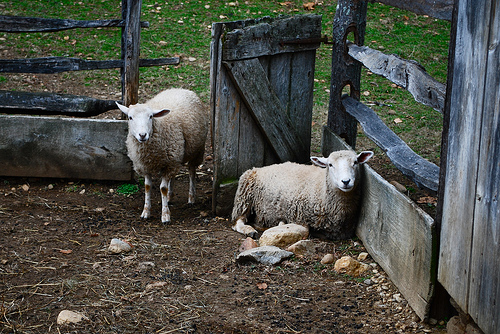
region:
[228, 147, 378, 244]
White sheep laying on the ground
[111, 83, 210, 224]
White sheep on its feet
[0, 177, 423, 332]
Ground of pebbles and soil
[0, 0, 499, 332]
Pen of wooden plants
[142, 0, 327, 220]
Open door of a pen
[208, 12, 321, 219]
Wooden frame of a door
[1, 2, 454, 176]
Short green grass with dry leaves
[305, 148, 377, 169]
Straight pointed ears of a sheep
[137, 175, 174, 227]
White legs with colored knees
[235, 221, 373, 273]
Huddled pieces of rock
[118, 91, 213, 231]
white sheep in wood pen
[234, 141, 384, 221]
white sheep in wood pen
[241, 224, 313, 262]
small rocks on pen floor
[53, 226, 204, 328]
brown sticks and hay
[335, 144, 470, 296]
wooden plans around pen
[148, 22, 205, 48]
green grass growing around pen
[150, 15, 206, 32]
dead leaves laying in grass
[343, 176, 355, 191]
black nsoe of white sheep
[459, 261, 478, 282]
nails in wooden boards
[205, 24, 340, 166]
small door of fence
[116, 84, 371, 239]
two sheep hanging out together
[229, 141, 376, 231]
sheep laying on the ground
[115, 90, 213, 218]
sheep standing next to door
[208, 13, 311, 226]
open wood door to the fenced in area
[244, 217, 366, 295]
rocks next to sheep laying down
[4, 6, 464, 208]
wood planks of the fencing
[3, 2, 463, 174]
grass behind the fenced in area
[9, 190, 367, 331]
straw scattered on the ground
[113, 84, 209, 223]
A sheep standing in dirt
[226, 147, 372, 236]
A sheep laying on the ground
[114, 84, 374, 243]
A pair of sheep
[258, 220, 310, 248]
A large rock on the ground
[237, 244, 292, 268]
A large rock on the ground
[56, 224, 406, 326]
some rocks on the ground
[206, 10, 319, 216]
A small wooden gate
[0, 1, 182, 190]
a small wooden fence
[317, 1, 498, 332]
a small wooden fence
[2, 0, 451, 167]
a grassy landscape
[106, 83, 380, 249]
Two sheep in a pen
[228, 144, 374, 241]
a sheep laying down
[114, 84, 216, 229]
a sheep standing by a wooden gate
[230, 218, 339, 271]
the sheep is laying next to a group of big rocks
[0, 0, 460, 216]
the fence is old and wooden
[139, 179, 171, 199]
the sheep's knees are brown